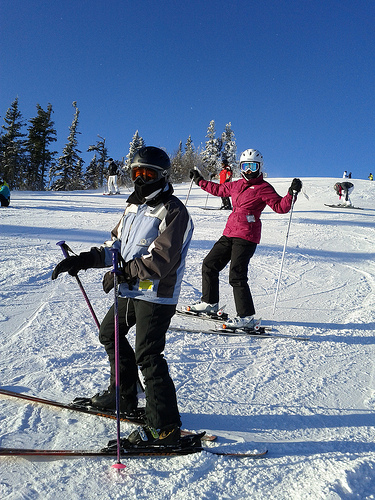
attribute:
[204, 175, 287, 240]
coat — pink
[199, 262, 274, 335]
boots — white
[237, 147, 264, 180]
helmet — silver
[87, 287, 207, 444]
pants — black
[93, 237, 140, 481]
pole — pink, purple, blue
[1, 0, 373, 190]
sky — blue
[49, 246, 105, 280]
glove — black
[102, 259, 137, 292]
glove — black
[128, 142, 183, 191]
helmet — black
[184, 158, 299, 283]
poles — ski poles, white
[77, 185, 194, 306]
coat — blue, black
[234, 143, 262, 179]
helmet — white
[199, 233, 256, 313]
pants — black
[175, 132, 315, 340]
person — red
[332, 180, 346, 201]
scarf — red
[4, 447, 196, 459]
writing — orange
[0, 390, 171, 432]
writing — orange